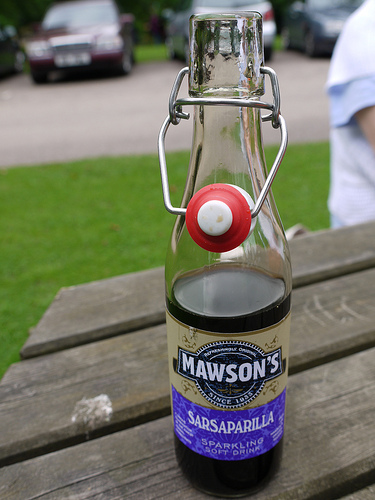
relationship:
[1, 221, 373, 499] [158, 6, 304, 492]
table under bottle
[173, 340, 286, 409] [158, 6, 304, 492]
label on bottle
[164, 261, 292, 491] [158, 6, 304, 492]
liquid in bottle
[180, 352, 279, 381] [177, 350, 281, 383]
mawson's on label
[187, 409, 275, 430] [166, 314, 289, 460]
word sarsaparilla on label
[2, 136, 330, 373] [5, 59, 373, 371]
grass on ground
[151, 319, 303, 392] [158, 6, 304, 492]
label on bottle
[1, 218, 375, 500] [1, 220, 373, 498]
picnic table on picnic table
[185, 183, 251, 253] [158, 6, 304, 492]
cover of bottle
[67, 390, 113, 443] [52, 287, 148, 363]
bird dropping on table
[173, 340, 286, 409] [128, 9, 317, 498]
label on beverage bottle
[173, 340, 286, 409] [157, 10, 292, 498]
label of beverage bottle